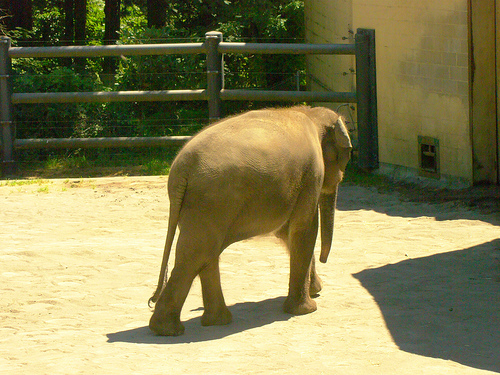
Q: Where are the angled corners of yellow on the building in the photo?
A: Near the fence.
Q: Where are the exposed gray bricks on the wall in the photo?
A: Right of building.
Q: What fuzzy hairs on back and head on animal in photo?
A: Brown fuzzy hairs.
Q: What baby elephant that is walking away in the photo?
A: Brown baby elephant.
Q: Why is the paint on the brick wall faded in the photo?
A: Brick wall needs painting again.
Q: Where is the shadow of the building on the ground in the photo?
A: Near baby elephant.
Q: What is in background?
A: Wooden fence.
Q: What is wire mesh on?
A: Fence.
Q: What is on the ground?
A: Dirt.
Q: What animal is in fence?
A: Elephant.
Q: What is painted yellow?
A: Brick wall.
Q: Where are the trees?
A: Background.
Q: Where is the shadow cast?
A: On ground.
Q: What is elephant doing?
A: Walking away.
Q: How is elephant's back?
A: Turned away.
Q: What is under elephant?
A: Shadow.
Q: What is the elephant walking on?
A: The ground.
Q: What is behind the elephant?
A: A fence.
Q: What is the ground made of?
A: Dirt.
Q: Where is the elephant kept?
A: Zoo.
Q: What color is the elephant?
A: Grey.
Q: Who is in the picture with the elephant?
A: No one.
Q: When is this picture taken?
A: Summer.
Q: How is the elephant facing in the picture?
A: Facing away.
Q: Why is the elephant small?
A: It's a baby.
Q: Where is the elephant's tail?
A: Behind it.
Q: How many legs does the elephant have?
A: Four.